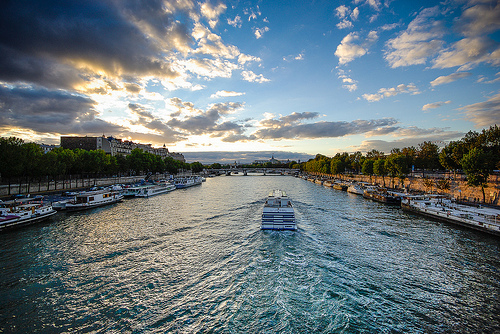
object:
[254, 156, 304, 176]
building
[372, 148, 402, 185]
tree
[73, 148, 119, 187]
tree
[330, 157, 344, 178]
tree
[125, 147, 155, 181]
tree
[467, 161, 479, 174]
section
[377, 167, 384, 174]
section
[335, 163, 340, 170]
section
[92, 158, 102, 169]
section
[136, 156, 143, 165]
section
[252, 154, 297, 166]
building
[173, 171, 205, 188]
boat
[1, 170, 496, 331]
water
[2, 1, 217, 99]
cloud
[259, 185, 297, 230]
boat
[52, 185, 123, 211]
boat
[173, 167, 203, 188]
boat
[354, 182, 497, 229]
boats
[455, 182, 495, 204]
dirt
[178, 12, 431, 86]
clouds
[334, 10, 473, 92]
clouds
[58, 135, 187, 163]
buildings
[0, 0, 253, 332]
left side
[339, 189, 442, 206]
bank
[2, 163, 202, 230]
boats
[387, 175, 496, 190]
ground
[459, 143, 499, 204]
tree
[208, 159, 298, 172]
bridge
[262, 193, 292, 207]
people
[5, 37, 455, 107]
sky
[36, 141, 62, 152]
hills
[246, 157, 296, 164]
hills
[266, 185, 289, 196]
section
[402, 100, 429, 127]
ground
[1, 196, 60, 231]
boat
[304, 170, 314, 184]
boat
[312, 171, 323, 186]
boat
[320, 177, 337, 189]
boat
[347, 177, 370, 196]
boat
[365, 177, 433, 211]
boat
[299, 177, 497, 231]
side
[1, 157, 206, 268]
side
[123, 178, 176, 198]
boat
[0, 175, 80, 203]
bank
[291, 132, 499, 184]
trees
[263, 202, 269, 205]
person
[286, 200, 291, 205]
person